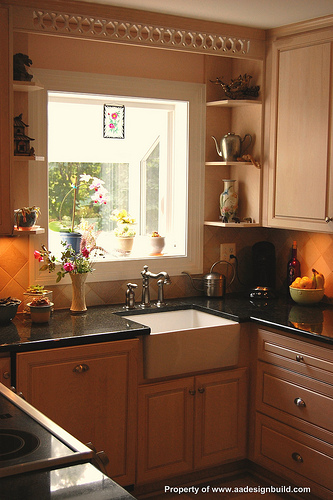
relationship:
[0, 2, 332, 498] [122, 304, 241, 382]
kitchen has a sink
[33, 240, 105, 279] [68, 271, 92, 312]
flowers are in a vase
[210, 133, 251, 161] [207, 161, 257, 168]
teapot on a shelf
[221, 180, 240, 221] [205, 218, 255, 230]
vase on a shelf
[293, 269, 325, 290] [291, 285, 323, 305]
fruit in a bowl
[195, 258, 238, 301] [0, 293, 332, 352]
watering can on counter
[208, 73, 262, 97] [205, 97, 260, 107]
plant on a shelf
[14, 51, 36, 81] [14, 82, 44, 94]
sculpture on a shelf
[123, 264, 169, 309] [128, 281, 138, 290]
faucet has a handle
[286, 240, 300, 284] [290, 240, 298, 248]
bottle has a cork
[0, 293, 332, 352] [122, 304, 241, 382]
counter has a sink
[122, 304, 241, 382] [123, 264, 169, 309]
sink has a faucet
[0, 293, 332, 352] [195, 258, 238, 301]
counter has a watering can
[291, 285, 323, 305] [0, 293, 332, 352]
bowl on counter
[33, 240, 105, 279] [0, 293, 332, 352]
flowers are on counter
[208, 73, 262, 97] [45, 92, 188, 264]
plant near window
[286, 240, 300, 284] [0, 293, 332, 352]
bottle on counter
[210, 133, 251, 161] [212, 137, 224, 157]
teapot has a spout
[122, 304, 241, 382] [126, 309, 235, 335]
sink has a inside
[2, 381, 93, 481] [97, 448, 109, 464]
stove has a knob